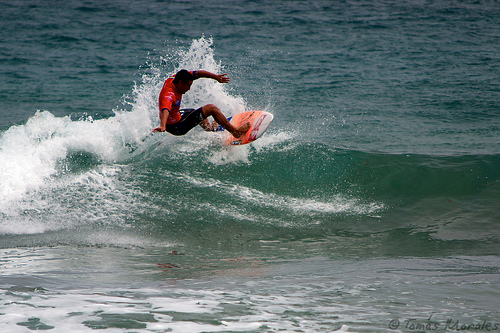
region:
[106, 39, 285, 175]
man surfing in ocean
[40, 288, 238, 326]
white foam on ocean's surface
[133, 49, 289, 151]
man wearing an orange shirt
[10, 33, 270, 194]
white foam of crashing ocean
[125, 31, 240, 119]
water spray caused by surfer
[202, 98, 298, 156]
orange and white surfboard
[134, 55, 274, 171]
man with arms out for balance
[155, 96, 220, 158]
man wearing black shorts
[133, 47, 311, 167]
man looking down at surfboard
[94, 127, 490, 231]
ocean wave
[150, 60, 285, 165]
A man on a surf board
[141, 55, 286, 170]
A man riding a wave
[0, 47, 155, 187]
Whitewater on top of a wave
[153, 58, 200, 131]
A man in a red shirt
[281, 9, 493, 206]
A green ocean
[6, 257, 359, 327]
Foamy ocean water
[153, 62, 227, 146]
A surfing man wearing black shorts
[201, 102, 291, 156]
A surfboard with orange, white, red and blue colors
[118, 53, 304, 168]
A man balancing on a surf board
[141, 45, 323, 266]
A man riding the waves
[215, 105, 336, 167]
the board is orange and white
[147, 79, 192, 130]
the shirt is red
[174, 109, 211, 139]
the shorts are black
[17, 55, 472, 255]
the sea has waves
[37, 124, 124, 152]
the water is white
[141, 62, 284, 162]
the guy is white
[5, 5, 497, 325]
the scene is outdoors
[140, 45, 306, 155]
the person is male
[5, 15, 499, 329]
it is daytime in the photo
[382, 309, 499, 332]
signature is at the bottom of the photo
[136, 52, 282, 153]
Man surfing in the ocean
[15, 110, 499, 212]
Small wave in the ocean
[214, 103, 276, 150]
Orange and white surf board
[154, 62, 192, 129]
Red shirt worn by a surfer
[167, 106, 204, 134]
Black shorts worn by a surfer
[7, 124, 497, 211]
Cresting wave in the ocean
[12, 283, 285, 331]
Foam in the water at the beach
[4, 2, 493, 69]
Large body of water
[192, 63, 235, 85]
Arm extended to maintain balance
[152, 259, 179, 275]
Seaweed in the ocean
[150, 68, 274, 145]
a surfer on a wave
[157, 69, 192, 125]
a surfer wearing a red wetsuit top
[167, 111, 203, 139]
a black wetsuit shorts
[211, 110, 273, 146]
the surfboard is white, orange and blu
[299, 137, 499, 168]
the crest of the wave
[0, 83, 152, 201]
the white water splash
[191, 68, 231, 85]
the surfers arm is extended for balance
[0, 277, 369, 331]
white foamy backwash from the wave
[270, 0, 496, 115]
dark deep blue ocean in the distance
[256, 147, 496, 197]
the wave appear dark green